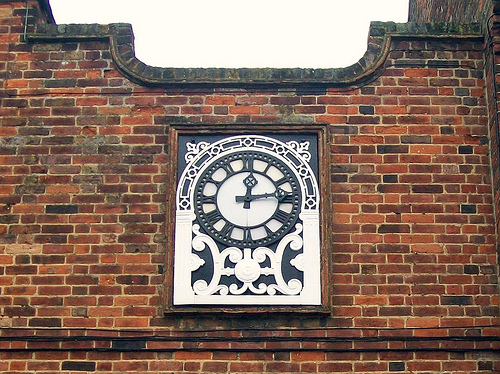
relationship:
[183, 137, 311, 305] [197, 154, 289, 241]
frame in clock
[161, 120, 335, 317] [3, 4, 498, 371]
clock set in wall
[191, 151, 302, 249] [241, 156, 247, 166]
clock has number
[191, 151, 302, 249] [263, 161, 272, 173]
clock has number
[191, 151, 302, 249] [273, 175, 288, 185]
clock has number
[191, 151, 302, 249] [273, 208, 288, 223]
clock has number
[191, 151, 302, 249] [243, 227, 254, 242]
clock has numeral six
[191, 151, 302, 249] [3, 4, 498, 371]
clock on wall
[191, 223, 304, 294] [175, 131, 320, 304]
scroll on clock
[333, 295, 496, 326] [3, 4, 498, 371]
brick in wall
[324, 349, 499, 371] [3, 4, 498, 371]
brick in wall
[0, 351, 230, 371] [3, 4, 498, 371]
brick in wall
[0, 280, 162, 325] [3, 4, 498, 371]
brick in wall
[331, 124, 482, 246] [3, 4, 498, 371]
brick in wall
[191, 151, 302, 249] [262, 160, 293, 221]
clock uses roman numerals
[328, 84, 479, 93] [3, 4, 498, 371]
bricks on top of wall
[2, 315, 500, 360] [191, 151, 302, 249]
ledge below clock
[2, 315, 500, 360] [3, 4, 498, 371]
ledge on wall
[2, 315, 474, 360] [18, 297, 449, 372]
ledge on a wall